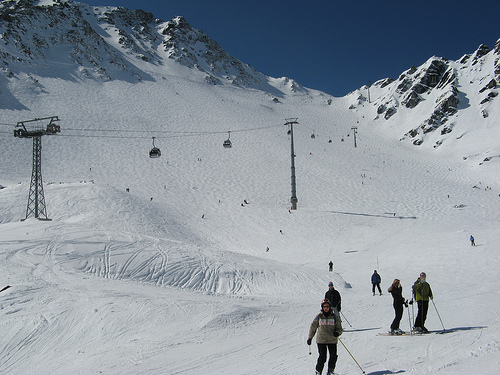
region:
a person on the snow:
[303, 299, 349, 374]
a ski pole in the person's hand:
[303, 335, 315, 357]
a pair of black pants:
[307, 339, 341, 374]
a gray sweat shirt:
[303, 309, 344, 348]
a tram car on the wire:
[146, 132, 163, 162]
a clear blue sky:
[76, 0, 498, 99]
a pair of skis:
[373, 325, 425, 342]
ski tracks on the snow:
[114, 236, 168, 284]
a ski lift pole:
[10, 113, 65, 225]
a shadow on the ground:
[300, 203, 417, 223]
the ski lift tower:
[11, 116, 61, 221]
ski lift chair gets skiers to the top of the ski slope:
[149, 136, 161, 159]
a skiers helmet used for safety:
[321, 297, 332, 307]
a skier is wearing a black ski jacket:
[388, 278, 405, 333]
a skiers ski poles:
[403, 298, 415, 333]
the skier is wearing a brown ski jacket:
[306, 311, 343, 343]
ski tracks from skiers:
[77, 238, 264, 296]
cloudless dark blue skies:
[98, 0, 499, 96]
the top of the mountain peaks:
[1, 0, 186, 96]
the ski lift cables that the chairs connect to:
[1, 118, 294, 139]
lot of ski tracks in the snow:
[155, 248, 231, 295]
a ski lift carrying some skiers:
[146, 131, 166, 161]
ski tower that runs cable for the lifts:
[12, 111, 63, 224]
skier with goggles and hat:
[304, 298, 344, 373]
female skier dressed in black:
[378, 275, 417, 345]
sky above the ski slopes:
[321, 17, 386, 77]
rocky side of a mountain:
[397, 51, 474, 113]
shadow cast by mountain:
[54, 48, 160, 88]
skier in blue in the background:
[466, 230, 481, 254]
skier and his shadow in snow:
[412, 271, 485, 341]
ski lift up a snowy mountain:
[17, 108, 361, 194]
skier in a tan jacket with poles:
[308, 299, 358, 368]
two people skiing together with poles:
[384, 261, 445, 343]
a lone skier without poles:
[357, 261, 384, 302]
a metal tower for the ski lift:
[276, 110, 316, 232]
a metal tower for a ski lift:
[6, 105, 85, 240]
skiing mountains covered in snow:
[339, 29, 491, 177]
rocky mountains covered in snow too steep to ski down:
[8, 13, 264, 98]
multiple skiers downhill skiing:
[289, 239, 476, 367]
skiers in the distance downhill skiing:
[89, 164, 313, 261]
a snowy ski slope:
[7, 72, 494, 374]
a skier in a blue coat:
[467, 226, 476, 251]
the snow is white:
[7, 232, 257, 373]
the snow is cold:
[14, 226, 288, 358]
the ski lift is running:
[59, 114, 385, 164]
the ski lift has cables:
[57, 119, 289, 146]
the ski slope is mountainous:
[359, 58, 496, 138]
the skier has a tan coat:
[300, 309, 347, 356]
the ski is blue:
[192, 2, 455, 78]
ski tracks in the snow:
[55, 230, 269, 312]